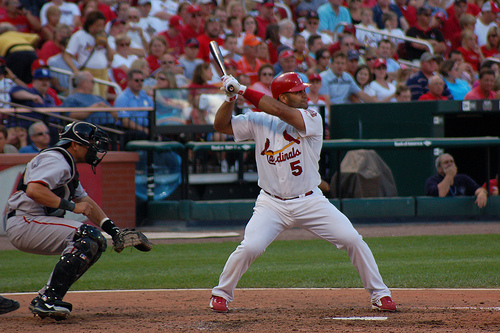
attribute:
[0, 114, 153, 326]
catcher — crouched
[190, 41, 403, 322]
baseball player — standing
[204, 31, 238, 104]
bat — black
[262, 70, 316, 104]
helmet — red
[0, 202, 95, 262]
pants — grey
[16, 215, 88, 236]
stripe — red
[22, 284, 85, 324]
shoes — red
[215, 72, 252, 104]
gloves — white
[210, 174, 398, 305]
pants — white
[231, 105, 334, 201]
shirt — white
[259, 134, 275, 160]
bird — red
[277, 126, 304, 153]
bird — red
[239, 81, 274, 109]
wrist band — red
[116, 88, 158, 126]
shirt — blue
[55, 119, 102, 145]
helmet — black